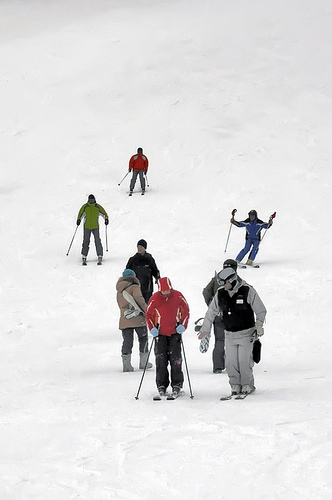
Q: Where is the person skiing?
A: White snow.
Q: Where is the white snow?
A: On the ground.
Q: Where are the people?
A: Bottom of the slope.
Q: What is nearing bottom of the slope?
A: The skier.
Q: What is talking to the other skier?
A: One skier.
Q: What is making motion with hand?
A: The skier.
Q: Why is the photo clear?
A: Its during the day.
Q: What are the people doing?
A: Skiing.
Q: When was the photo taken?
A: Daytime.